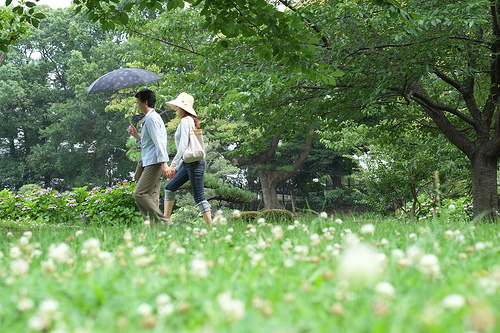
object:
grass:
[0, 232, 499, 332]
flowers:
[333, 226, 392, 298]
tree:
[340, 24, 500, 222]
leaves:
[329, 68, 348, 78]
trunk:
[435, 121, 499, 224]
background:
[0, 0, 500, 225]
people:
[130, 87, 171, 224]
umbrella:
[84, 65, 163, 134]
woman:
[163, 91, 212, 228]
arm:
[169, 118, 190, 167]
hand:
[160, 164, 172, 179]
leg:
[187, 164, 212, 228]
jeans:
[164, 159, 212, 214]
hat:
[164, 91, 199, 117]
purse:
[180, 117, 206, 163]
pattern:
[102, 72, 133, 88]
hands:
[168, 166, 175, 176]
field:
[0, 195, 499, 332]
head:
[170, 92, 195, 117]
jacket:
[137, 108, 169, 168]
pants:
[131, 163, 169, 228]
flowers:
[36, 183, 64, 212]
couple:
[126, 88, 214, 229]